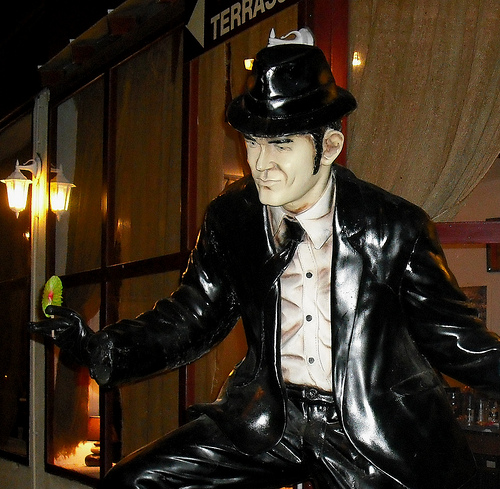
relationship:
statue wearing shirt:
[35, 27, 498, 479] [265, 203, 340, 399]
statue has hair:
[35, 27, 498, 479] [308, 131, 327, 174]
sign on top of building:
[178, 0, 300, 69] [1, 0, 498, 485]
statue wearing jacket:
[35, 27, 498, 479] [104, 182, 497, 438]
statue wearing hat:
[35, 27, 498, 479] [221, 40, 360, 135]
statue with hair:
[35, 27, 498, 479] [255, 107, 364, 175]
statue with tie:
[35, 27, 498, 479] [231, 214, 302, 314]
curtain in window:
[114, 40, 191, 460] [120, 110, 172, 222]